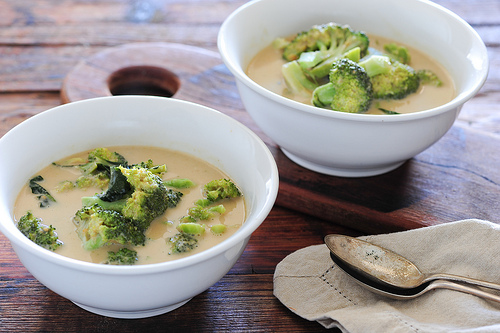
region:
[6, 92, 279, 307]
a plate of food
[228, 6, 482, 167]
a plate of food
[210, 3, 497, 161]
a plate of food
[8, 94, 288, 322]
a plate of food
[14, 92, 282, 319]
a plate of food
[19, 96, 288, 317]
a plate of food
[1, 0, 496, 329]
Two bowls and two spoons rest on a table.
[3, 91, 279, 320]
The white bowl contains soup.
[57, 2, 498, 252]
This bowl rests on a board.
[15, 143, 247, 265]
The broccoli floats in a creamy liquid.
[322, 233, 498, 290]
The spoon is dirty.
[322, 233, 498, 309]
One spoon is nestled upon another spoon.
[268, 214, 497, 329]
The spoons lay on a linen napkin.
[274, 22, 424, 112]
A group of green broccoli.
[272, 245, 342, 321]
The corner of the linen napkin.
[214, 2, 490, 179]
The bowl of soup is half-filled.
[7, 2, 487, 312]
two bowls of soup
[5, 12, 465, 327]
broccoli in the soup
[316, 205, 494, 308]
two spoons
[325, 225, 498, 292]
tarnish on the outside of spoon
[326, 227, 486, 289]
spoon made of silver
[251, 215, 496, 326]
white napkin on the table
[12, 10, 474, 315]
soup is in two white bowls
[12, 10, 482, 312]
wooden table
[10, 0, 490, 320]
table is a reddish-brown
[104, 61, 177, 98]
whole in table to place an umbrella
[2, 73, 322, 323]
A bowl of broccoli and cheese soup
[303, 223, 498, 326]
Two silver spoons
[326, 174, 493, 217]
A brown wooden board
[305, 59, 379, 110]
A piece of cooked broccoli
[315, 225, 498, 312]
Tarnished silver spoons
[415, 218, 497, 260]
Part of a white rag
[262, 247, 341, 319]
The corner of a white rag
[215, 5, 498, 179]
Broccoli and cheese soup in a white bowl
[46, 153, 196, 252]
Orange cheese soup with broccoli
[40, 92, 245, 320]
A bowl of soup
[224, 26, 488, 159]
A bowl of soup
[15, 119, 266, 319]
A white bowl with soup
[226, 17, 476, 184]
A white bowl with soup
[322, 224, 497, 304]
Two silver spoons on the table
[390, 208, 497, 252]
A white hand towel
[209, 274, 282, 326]
A brown table surface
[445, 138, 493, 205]
A brown table surface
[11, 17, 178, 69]
A brown table surface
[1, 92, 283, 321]
small white bowl on a wooden table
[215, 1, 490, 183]
small white bowl on a wooden table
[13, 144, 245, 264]
broccoli and cheese sauce in a small white bowl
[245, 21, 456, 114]
broccoli and cheese sauce in a small white bowl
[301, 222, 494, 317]
two spoons on top of cloth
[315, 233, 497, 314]
Two spoons are next to each other.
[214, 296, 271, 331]
The table is wooden.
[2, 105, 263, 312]
The bowl is white.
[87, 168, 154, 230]
The bowl has broccoli.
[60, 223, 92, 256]
The soup is creamy.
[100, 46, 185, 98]
The wooden piece has a handle.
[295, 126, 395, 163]
The bowl has curves.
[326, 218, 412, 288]
The spoon is dirty.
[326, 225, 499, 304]
spoon on a napkin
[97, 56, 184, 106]
hole in a table top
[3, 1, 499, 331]
table top made of wood